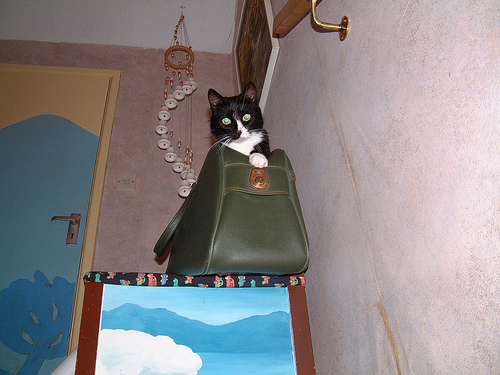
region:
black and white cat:
[207, 80, 270, 169]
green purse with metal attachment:
[158, 145, 310, 275]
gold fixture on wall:
[274, 0, 349, 40]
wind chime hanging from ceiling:
[153, 8, 199, 195]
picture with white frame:
[230, 2, 278, 113]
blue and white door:
[0, 65, 122, 373]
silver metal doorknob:
[48, 213, 76, 245]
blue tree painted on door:
[1, 269, 79, 374]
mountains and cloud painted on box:
[94, 288, 296, 374]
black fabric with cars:
[83, 270, 306, 286]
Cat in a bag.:
[105, 64, 362, 305]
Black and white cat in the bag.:
[194, 57, 288, 193]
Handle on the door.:
[28, 162, 132, 283]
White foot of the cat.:
[196, 74, 305, 215]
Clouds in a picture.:
[67, 257, 294, 373]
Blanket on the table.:
[76, 258, 330, 304]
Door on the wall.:
[35, 48, 175, 288]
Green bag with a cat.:
[115, 126, 439, 361]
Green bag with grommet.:
[144, 107, 343, 300]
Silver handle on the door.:
[31, 181, 152, 274]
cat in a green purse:
[159, 83, 336, 293]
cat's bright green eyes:
[217, 112, 266, 125]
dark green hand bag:
[150, 155, 329, 269]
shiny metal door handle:
[42, 205, 94, 250]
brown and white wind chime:
[146, 10, 213, 197]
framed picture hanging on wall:
[225, 5, 314, 106]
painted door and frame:
[0, 58, 109, 370]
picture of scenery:
[97, 282, 309, 372]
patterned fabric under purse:
[81, 265, 308, 300]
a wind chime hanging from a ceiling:
[156, 5, 201, 198]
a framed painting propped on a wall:
[78, 278, 315, 373]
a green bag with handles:
[153, 146, 310, 278]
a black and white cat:
[203, 83, 271, 165]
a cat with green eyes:
[221, 110, 252, 126]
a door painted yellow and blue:
[2, 60, 122, 372]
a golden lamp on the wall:
[272, 0, 349, 43]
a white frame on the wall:
[233, 0, 280, 118]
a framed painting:
[232, 0, 277, 118]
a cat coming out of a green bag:
[203, 86, 273, 166]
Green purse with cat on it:
[143, 140, 318, 290]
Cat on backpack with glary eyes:
[200, 80, 271, 167]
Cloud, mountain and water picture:
[95, 281, 305, 371]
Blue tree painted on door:
[0, 265, 75, 370]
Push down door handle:
[47, 210, 82, 245]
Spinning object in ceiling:
[155, 6, 200, 196]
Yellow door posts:
[0, 60, 121, 371]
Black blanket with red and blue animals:
[80, 267, 310, 287]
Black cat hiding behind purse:
[197, 77, 282, 167]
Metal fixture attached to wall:
[264, 1, 366, 39]